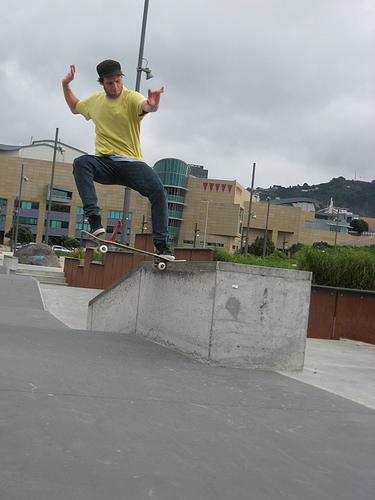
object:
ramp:
[84, 258, 156, 333]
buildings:
[239, 198, 375, 256]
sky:
[0, 0, 374, 190]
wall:
[85, 264, 218, 373]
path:
[0, 273, 374, 499]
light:
[141, 66, 153, 82]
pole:
[118, 0, 149, 248]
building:
[151, 158, 192, 258]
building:
[177, 174, 255, 261]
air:
[249, 87, 352, 159]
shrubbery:
[213, 242, 374, 291]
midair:
[59, 48, 187, 274]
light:
[22, 173, 30, 182]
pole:
[12, 160, 25, 248]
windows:
[30, 201, 41, 211]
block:
[86, 257, 313, 373]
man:
[60, 58, 177, 265]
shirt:
[74, 82, 151, 164]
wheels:
[99, 242, 109, 256]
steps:
[38, 280, 69, 288]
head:
[95, 58, 125, 100]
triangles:
[225, 183, 233, 195]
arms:
[126, 86, 159, 118]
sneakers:
[87, 214, 107, 238]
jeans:
[71, 152, 170, 246]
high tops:
[150, 231, 176, 262]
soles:
[90, 227, 107, 242]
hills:
[246, 176, 374, 218]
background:
[0, 0, 374, 499]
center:
[149, 157, 189, 246]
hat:
[95, 59, 124, 80]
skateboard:
[79, 226, 187, 272]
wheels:
[156, 259, 167, 273]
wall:
[61, 232, 373, 345]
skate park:
[0, 233, 374, 500]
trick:
[61, 59, 190, 271]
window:
[19, 201, 26, 209]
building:
[0, 138, 154, 251]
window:
[25, 201, 31, 210]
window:
[107, 208, 110, 218]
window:
[110, 209, 116, 220]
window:
[54, 220, 62, 229]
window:
[28, 218, 35, 226]